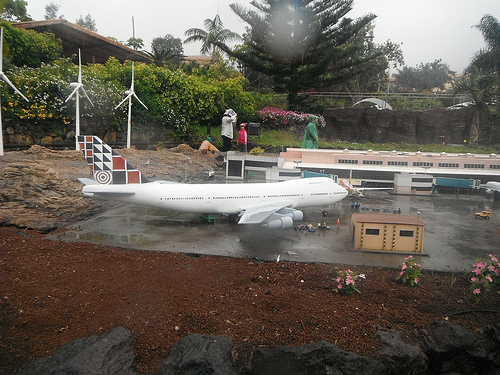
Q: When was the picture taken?
A: Daytime.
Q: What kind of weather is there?
A: Rain.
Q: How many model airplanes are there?
A: One.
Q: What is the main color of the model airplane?
A: White.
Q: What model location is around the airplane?
A: An airport.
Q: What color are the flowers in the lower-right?
A: Pink.